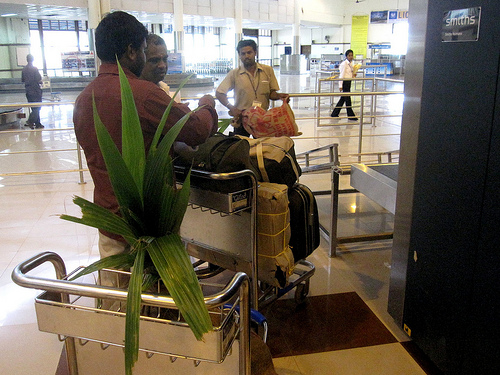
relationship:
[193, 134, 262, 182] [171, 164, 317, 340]
bag on cart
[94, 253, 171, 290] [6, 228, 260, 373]
basket on cart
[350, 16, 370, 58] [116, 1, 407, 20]
yellow banner hanging from ceiling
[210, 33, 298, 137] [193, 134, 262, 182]
man carrying bag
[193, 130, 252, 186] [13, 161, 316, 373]
bag on cart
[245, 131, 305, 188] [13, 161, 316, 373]
bag on cart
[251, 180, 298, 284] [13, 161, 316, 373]
bag on cart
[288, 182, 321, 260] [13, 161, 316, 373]
bag on cart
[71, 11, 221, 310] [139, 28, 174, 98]
man talking to man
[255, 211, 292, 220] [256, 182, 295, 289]
rope on bag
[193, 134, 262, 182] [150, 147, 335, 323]
bag on roller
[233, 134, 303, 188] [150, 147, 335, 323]
bag on roller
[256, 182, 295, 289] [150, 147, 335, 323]
bag on roller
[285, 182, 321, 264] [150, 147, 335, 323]
bag on roller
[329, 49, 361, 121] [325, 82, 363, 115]
man wearing black pants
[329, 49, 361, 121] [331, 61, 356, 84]
man wearing blouse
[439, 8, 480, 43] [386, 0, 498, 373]
sign on wall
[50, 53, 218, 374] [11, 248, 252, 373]
plant on cart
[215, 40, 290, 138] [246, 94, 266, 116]
man wearing badge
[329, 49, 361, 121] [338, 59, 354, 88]
man wearing blouse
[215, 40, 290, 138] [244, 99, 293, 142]
man holding bag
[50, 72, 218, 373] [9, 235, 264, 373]
plant in basket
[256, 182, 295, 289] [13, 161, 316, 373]
bag on cart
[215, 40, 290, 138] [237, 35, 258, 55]
man has black hair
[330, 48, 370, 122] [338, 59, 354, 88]
man wearing blouse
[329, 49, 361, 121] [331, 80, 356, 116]
man wearing black pants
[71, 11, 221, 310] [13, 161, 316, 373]
man standing next to cart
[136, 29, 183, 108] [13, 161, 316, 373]
man standing next to cart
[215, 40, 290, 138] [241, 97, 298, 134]
man holding bag